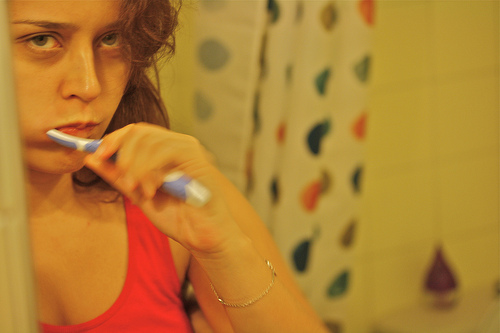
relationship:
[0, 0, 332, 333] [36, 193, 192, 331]
woman wearing shirt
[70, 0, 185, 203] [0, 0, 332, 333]
hair belonging to woman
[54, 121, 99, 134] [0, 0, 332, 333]
lip belonging to woman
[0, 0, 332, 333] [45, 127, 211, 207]
woman holding toothbrush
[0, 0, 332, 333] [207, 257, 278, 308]
woman wearing bracelet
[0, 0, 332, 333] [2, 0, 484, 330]
woman grooming in mirror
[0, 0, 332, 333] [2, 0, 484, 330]
woman looking in mirror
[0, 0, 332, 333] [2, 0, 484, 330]
woman brushing teeth in mirror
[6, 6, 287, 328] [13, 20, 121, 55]
woman with eyes